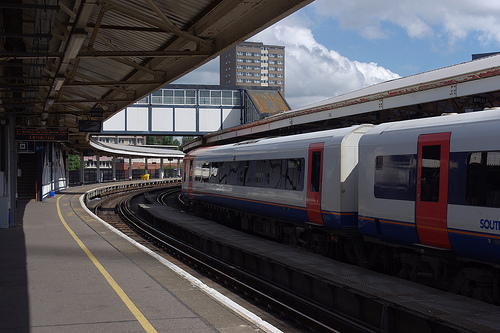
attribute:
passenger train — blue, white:
[177, 100, 485, 295]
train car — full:
[353, 100, 483, 281]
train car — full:
[176, 120, 376, 254]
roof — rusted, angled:
[243, 87, 292, 117]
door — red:
[414, 128, 453, 251]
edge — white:
[102, 219, 158, 257]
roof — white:
[200, 103, 490, 149]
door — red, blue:
[184, 133, 453, 235]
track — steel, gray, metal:
[92, 186, 498, 332]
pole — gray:
[5, 110, 20, 228]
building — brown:
[231, 41, 290, 85]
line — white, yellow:
[81, 178, 291, 333]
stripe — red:
[309, 142, 323, 224]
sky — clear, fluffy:
[181, 4, 498, 109]